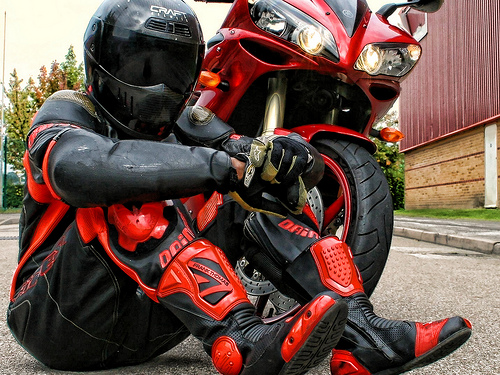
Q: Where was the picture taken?
A: It was taken at the pavement.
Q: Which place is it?
A: It is a pavement.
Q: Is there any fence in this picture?
A: No, there are no fences.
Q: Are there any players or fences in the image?
A: No, there are no fences or players.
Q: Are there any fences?
A: No, there are no fences.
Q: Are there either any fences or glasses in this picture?
A: No, there are no fences or glasses.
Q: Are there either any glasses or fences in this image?
A: No, there are no fences or glasses.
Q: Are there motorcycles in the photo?
A: Yes, there is a motorcycle.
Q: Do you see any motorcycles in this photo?
A: Yes, there is a motorcycle.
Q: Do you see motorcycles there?
A: Yes, there is a motorcycle.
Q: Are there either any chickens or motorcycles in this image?
A: Yes, there is a motorcycle.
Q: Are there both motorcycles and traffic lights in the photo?
A: No, there is a motorcycle but no traffic lights.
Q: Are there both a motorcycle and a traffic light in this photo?
A: No, there is a motorcycle but no traffic lights.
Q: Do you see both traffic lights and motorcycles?
A: No, there is a motorcycle but no traffic lights.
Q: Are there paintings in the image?
A: No, there are no paintings.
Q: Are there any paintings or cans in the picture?
A: No, there are no paintings or cans.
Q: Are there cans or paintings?
A: No, there are no paintings or cans.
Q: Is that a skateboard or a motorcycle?
A: That is a motorcycle.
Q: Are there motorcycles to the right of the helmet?
A: Yes, there is a motorcycle to the right of the helmet.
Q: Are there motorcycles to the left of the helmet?
A: No, the motorcycle is to the right of the helmet.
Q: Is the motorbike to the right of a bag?
A: No, the motorbike is to the right of the helmet.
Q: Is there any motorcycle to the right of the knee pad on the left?
A: Yes, there is a motorcycle to the right of the knee pad.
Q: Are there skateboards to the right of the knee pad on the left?
A: No, there is a motorcycle to the right of the knee pad.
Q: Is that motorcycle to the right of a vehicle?
A: No, the motorcycle is to the right of a knee pad.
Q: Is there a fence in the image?
A: No, there are no fences.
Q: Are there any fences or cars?
A: No, there are no fences or cars.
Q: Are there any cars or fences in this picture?
A: No, there are no fences or cars.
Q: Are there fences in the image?
A: No, there are no fences.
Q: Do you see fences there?
A: No, there are no fences.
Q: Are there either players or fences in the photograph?
A: No, there are no fences or players.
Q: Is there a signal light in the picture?
A: No, there are no traffic lights.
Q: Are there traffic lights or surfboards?
A: No, there are no traffic lights or surfboards.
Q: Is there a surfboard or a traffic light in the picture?
A: No, there are no traffic lights or surfboards.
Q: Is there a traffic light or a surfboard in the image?
A: No, there are no traffic lights or surfboards.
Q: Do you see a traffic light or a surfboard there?
A: No, there are no traffic lights or surfboards.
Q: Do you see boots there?
A: Yes, there are boots.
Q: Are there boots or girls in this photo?
A: Yes, there are boots.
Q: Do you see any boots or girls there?
A: Yes, there are boots.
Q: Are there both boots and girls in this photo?
A: No, there are boots but no girls.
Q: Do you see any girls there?
A: No, there are no girls.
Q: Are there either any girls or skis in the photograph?
A: No, there are no girls or skis.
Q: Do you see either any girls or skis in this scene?
A: No, there are no girls or skis.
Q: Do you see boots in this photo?
A: Yes, there are boots.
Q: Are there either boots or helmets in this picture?
A: Yes, there are boots.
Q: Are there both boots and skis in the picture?
A: No, there are boots but no skis.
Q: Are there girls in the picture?
A: No, there are no girls.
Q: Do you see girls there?
A: No, there are no girls.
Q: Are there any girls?
A: No, there are no girls.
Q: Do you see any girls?
A: No, there are no girls.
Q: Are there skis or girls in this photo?
A: No, there are no girls or skis.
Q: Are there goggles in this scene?
A: Yes, there are goggles.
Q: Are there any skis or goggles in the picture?
A: Yes, there are goggles.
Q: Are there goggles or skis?
A: Yes, there are goggles.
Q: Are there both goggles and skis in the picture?
A: No, there are goggles but no skis.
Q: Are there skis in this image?
A: No, there are no skis.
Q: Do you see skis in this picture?
A: No, there are no skis.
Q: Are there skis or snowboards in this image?
A: No, there are no skis or snowboards.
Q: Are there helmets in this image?
A: Yes, there is a helmet.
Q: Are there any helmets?
A: Yes, there is a helmet.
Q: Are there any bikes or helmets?
A: Yes, there is a helmet.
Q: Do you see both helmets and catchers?
A: No, there is a helmet but no catchers.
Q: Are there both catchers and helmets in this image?
A: No, there is a helmet but no catchers.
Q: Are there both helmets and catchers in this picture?
A: No, there is a helmet but no catchers.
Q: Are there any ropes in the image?
A: No, there are no ropes.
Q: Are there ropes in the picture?
A: No, there are no ropes.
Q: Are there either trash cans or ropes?
A: No, there are no ropes or trash cans.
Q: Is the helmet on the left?
A: Yes, the helmet is on the left of the image.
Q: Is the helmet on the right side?
A: No, the helmet is on the left of the image.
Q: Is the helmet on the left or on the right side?
A: The helmet is on the left of the image.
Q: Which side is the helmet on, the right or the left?
A: The helmet is on the left of the image.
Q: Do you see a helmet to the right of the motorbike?
A: No, the helmet is to the left of the motorbike.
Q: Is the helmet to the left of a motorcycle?
A: Yes, the helmet is to the left of a motorcycle.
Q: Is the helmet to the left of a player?
A: No, the helmet is to the left of a motorcycle.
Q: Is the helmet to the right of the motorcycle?
A: No, the helmet is to the left of the motorcycle.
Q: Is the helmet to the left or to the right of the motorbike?
A: The helmet is to the left of the motorbike.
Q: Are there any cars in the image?
A: No, there are no cars.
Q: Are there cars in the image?
A: No, there are no cars.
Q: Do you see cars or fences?
A: No, there are no cars or fences.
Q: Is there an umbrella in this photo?
A: No, there are no umbrellas.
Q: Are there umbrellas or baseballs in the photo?
A: No, there are no umbrellas or baseballs.